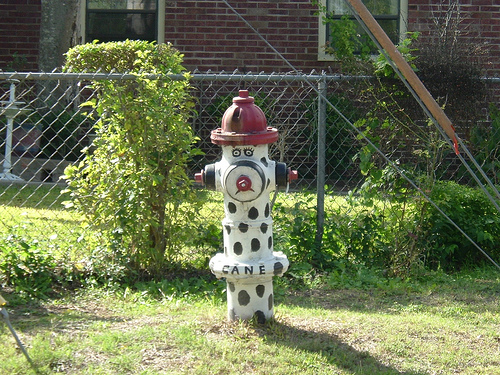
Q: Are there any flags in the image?
A: No, there are no flags.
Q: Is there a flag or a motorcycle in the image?
A: No, there are no flags or motorcycles.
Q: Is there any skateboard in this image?
A: No, there are no skateboards.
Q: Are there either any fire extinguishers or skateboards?
A: No, there are no skateboards or fire extinguishers.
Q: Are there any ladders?
A: No, there are no ladders.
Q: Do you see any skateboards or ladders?
A: No, there are no ladders or skateboards.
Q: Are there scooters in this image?
A: No, there are no scooters.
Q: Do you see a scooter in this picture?
A: No, there are no scooters.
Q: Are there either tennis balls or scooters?
A: No, there are no scooters or tennis balls.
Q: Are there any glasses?
A: No, there are no glasses.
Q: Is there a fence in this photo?
A: Yes, there is a fence.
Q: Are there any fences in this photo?
A: Yes, there is a fence.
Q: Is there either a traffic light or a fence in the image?
A: Yes, there is a fence.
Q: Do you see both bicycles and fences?
A: No, there is a fence but no bicycles.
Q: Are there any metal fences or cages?
A: Yes, there is a metal fence.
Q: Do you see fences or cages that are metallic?
A: Yes, the fence is metallic.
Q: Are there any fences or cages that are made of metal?
A: Yes, the fence is made of metal.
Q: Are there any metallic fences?
A: Yes, there is a metal fence.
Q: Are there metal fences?
A: Yes, there is a metal fence.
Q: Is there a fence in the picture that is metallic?
A: Yes, there is a fence that is metallic.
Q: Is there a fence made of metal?
A: Yes, there is a fence that is made of metal.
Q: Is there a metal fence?
A: Yes, there is a fence that is made of metal.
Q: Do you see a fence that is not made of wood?
A: Yes, there is a fence that is made of metal.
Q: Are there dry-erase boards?
A: No, there are no dry-erase boards.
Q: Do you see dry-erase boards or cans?
A: No, there are no dry-erase boards or cans.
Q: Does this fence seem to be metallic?
A: Yes, the fence is metallic.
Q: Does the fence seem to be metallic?
A: Yes, the fence is metallic.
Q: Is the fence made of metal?
A: Yes, the fence is made of metal.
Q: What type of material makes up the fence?
A: The fence is made of metal.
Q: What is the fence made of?
A: The fence is made of metal.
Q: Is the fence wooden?
A: No, the fence is metallic.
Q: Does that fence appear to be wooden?
A: No, the fence is metallic.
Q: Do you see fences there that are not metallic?
A: No, there is a fence but it is metallic.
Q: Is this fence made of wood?
A: No, the fence is made of metal.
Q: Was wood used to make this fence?
A: No, the fence is made of metal.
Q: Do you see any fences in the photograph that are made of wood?
A: No, there is a fence but it is made of metal.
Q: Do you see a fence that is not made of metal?
A: No, there is a fence but it is made of metal.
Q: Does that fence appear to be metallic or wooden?
A: The fence is metallic.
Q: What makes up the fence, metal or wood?
A: The fence is made of metal.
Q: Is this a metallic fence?
A: Yes, this is a metallic fence.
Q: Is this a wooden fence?
A: No, this is a metallic fence.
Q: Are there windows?
A: Yes, there is a window.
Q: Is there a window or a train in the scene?
A: Yes, there is a window.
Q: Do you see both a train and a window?
A: No, there is a window but no trains.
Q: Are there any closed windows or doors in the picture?
A: Yes, there is a closed window.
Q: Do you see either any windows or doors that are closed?
A: Yes, the window is closed.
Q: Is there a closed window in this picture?
A: Yes, there is a closed window.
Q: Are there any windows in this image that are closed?
A: Yes, there is a window that is closed.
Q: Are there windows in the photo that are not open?
A: Yes, there is an closed window.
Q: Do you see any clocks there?
A: No, there are no clocks.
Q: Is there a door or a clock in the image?
A: No, there are no clocks or doors.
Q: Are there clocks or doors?
A: No, there are no clocks or doors.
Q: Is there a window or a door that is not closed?
A: No, there is a window but it is closed.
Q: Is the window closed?
A: Yes, the window is closed.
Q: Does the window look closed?
A: Yes, the window is closed.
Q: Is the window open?
A: No, the window is closed.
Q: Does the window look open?
A: No, the window is closed.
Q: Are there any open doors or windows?
A: No, there is a window but it is closed.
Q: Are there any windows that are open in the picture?
A: No, there is a window but it is closed.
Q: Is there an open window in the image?
A: No, there is a window but it is closed.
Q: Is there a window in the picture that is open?
A: No, there is a window but it is closed.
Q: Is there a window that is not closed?
A: No, there is a window but it is closed.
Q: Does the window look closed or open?
A: The window is closed.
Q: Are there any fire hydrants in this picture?
A: Yes, there is a fire hydrant.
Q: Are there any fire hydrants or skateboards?
A: Yes, there is a fire hydrant.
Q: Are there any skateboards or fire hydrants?
A: Yes, there is a fire hydrant.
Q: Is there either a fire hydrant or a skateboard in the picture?
A: Yes, there is a fire hydrant.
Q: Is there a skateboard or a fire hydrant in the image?
A: Yes, there is a fire hydrant.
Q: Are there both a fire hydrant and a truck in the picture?
A: No, there is a fire hydrant but no trucks.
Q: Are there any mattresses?
A: No, there are no mattresses.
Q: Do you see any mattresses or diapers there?
A: No, there are no mattresses or diapers.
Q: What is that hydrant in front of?
A: The hydrant is in front of the bush.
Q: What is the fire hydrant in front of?
A: The hydrant is in front of the bush.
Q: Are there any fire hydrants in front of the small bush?
A: Yes, there is a fire hydrant in front of the shrub.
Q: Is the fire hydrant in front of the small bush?
A: Yes, the fire hydrant is in front of the bush.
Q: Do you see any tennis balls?
A: No, there are no tennis balls.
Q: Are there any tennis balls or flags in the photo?
A: No, there are no tennis balls or flags.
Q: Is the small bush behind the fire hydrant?
A: Yes, the bush is behind the fire hydrant.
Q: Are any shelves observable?
A: No, there are no shelves.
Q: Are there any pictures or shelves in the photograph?
A: No, there are no shelves or pictures.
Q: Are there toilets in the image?
A: No, there are no toilets.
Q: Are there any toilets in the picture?
A: No, there are no toilets.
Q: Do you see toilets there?
A: No, there are no toilets.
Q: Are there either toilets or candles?
A: No, there are no toilets or candles.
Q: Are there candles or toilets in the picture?
A: No, there are no toilets or candles.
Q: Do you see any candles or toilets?
A: No, there are no toilets or candles.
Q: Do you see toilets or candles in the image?
A: No, there are no toilets or candles.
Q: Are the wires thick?
A: Yes, the wires are thick.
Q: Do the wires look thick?
A: Yes, the wires are thick.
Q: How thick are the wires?
A: The wires are thick.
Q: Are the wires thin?
A: No, the wires are thick.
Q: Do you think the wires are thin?
A: No, the wires are thick.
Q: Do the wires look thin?
A: No, the wires are thick.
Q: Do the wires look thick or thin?
A: The wires are thick.